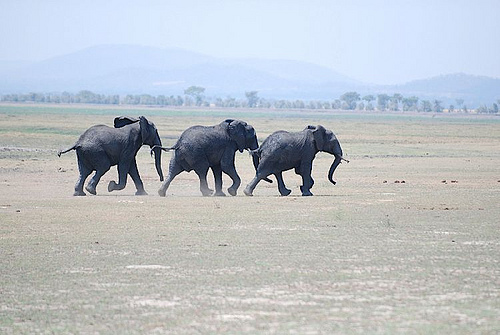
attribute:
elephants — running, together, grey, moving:
[54, 114, 347, 198]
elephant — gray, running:
[57, 114, 163, 199]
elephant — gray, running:
[151, 120, 272, 198]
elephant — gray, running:
[244, 125, 350, 199]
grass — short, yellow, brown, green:
[1, 103, 499, 333]